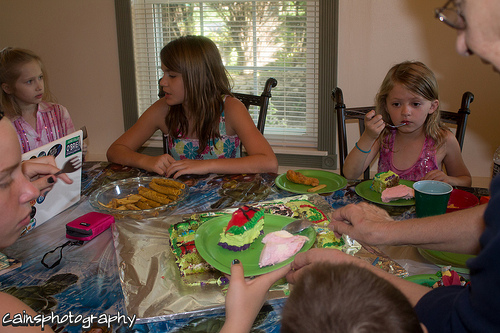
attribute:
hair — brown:
[154, 33, 232, 156]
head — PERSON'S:
[269, 256, 428, 323]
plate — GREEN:
[186, 204, 319, 275]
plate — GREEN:
[190, 200, 318, 283]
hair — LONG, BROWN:
[158, 37, 237, 152]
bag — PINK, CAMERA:
[50, 201, 115, 247]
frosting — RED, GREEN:
[222, 203, 260, 243]